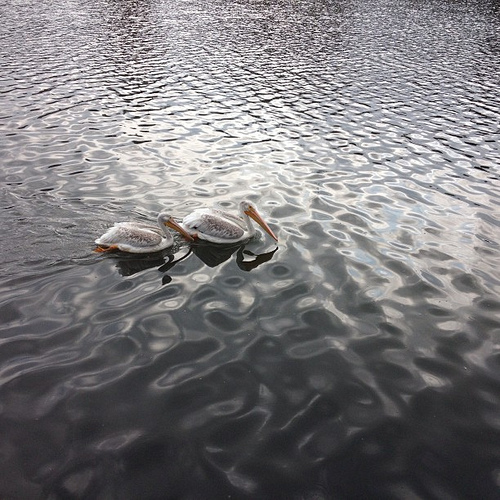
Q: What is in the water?
A: Geese.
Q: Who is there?
A: No one.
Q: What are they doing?
A: Swimming.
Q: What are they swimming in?
A: Water.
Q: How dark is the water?
A: Very dark.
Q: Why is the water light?
A: Reflection.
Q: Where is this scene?
A: A lake scene.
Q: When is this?
A: Daytime.